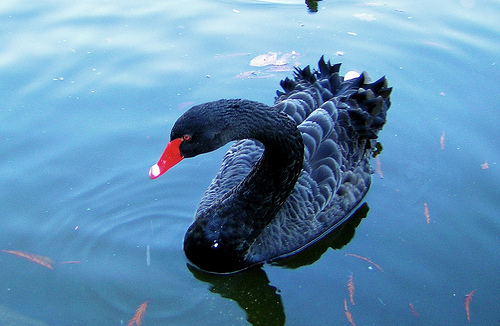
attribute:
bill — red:
[148, 137, 184, 178]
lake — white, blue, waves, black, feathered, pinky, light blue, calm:
[1, 1, 500, 323]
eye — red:
[182, 133, 190, 140]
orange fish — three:
[434, 127, 447, 162]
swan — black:
[134, 45, 434, 273]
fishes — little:
[424, 124, 484, 184]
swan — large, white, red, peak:
[121, 25, 484, 311]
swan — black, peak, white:
[140, 40, 429, 297]